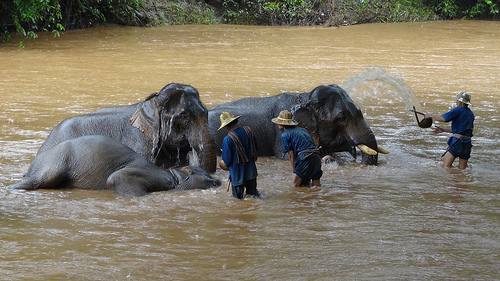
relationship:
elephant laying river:
[17, 137, 247, 220] [23, 22, 496, 262]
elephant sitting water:
[5, 135, 223, 198] [26, 30, 496, 279]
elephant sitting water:
[23, 83, 217, 180] [26, 30, 496, 279]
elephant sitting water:
[207, 83, 390, 165] [26, 30, 496, 279]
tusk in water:
[359, 144, 378, 154] [3, 66, 498, 277]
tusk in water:
[376, 145, 390, 156] [3, 66, 498, 277]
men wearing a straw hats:
[218, 111, 260, 201] [451, 91, 471, 101]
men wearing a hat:
[273, 110, 324, 190] [271, 110, 299, 125]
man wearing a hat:
[424, 92, 473, 170] [216, 112, 243, 132]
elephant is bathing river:
[5, 135, 223, 198] [1, 18, 499, 278]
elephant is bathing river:
[23, 83, 217, 180] [1, 18, 499, 278]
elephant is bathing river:
[207, 83, 390, 165] [1, 18, 499, 278]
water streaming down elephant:
[143, 97, 213, 169] [23, 83, 217, 180]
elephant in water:
[5, 135, 223, 198] [26, 30, 496, 279]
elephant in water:
[193, 64, 400, 194] [26, 30, 496, 279]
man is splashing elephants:
[388, 83, 493, 189] [2, 81, 391, 202]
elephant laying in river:
[5, 135, 223, 198] [1, 18, 499, 278]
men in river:
[218, 111, 260, 201] [11, 17, 463, 263]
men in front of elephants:
[209, 111, 383, 209] [96, 71, 391, 175]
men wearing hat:
[273, 110, 329, 190] [269, 108, 299, 125]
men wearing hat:
[218, 111, 260, 201] [216, 110, 240, 131]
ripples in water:
[0, 20, 499, 279] [26, 30, 496, 279]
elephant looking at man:
[30, 81, 216, 181] [219, 110, 264, 197]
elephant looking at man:
[5, 135, 223, 198] [219, 110, 264, 197]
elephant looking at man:
[207, 83, 390, 165] [273, 112, 322, 187]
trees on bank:
[0, 0, 498, 49] [0, 17, 499, 43]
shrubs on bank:
[0, 0, 494, 25] [0, 17, 499, 43]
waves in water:
[385, 144, 431, 171] [26, 30, 496, 279]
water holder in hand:
[404, 109, 456, 134] [416, 110, 466, 138]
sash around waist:
[292, 147, 322, 162] [279, 130, 324, 172]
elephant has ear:
[23, 83, 217, 180] [114, 98, 164, 160]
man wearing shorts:
[424, 92, 473, 170] [439, 131, 484, 161]